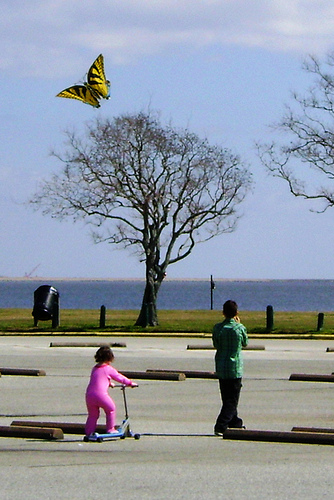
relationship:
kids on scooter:
[79, 341, 133, 446] [82, 375, 146, 443]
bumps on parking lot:
[10, 339, 333, 451] [3, 333, 332, 496]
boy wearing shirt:
[205, 295, 263, 440] [204, 317, 254, 380]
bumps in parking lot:
[10, 339, 333, 451] [3, 333, 332, 496]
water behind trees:
[2, 278, 334, 309] [26, 39, 333, 329]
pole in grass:
[205, 275, 222, 311] [0, 308, 333, 332]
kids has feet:
[79, 341, 133, 446] [78, 423, 117, 440]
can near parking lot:
[30, 284, 65, 327] [3, 333, 332, 496]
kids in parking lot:
[65, 293, 264, 449] [3, 333, 332, 496]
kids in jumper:
[79, 341, 133, 446] [82, 362, 126, 432]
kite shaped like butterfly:
[43, 51, 127, 115] [47, 53, 127, 114]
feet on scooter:
[78, 423, 117, 440] [82, 375, 146, 443]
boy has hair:
[205, 295, 263, 440] [219, 297, 240, 318]